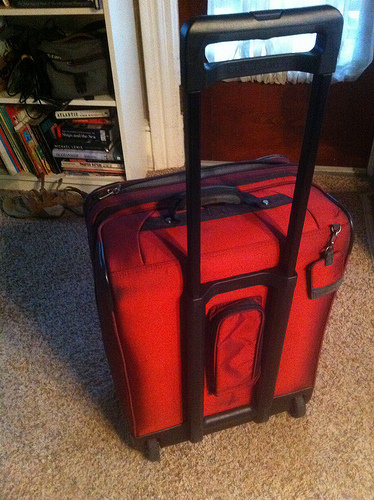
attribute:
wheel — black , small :
[144, 438, 163, 462]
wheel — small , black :
[291, 394, 309, 417]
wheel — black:
[292, 390, 306, 415]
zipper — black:
[322, 223, 343, 265]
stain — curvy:
[224, 314, 248, 382]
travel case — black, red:
[85, 7, 351, 462]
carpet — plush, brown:
[1, 196, 373, 499]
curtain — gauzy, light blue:
[207, 1, 372, 81]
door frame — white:
[104, 1, 185, 179]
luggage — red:
[78, 5, 360, 464]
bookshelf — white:
[1, 1, 149, 194]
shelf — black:
[0, 93, 115, 109]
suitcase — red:
[81, 4, 353, 464]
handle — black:
[178, 2, 345, 279]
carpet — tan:
[2, 168, 361, 498]